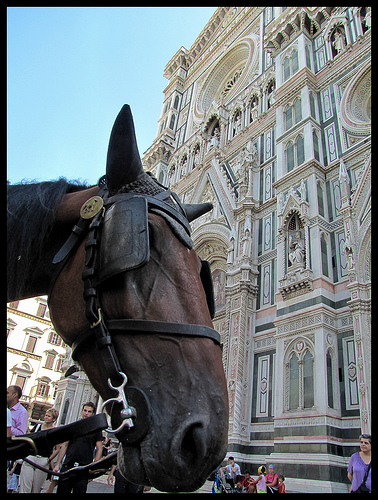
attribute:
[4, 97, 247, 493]
horse — brown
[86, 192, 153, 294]
blinders — leather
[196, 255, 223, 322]
blinders — leather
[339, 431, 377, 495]
woman — standing, in purple, alone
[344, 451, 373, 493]
top — purple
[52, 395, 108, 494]
people — standing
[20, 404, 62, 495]
people — standing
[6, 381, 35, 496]
people — standing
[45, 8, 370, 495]
building — tall, ornate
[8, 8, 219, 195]
sky — blue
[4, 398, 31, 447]
shirt — pink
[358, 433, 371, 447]
hair — short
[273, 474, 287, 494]
people — sitting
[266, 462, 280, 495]
people — sitting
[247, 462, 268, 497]
people — sitting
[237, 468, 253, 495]
people — sitting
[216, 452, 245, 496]
people — sitting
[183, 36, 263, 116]
window — large, round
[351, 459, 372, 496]
bag — black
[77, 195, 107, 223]
piece — round, gold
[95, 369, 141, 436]
clasp — silver, metal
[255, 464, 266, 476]
hat — yellow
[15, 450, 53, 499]
pants — khaki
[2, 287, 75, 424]
building — beside